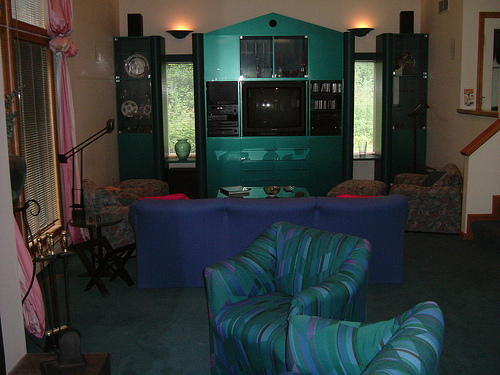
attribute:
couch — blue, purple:
[171, 212, 255, 243]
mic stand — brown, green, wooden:
[70, 137, 106, 224]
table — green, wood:
[87, 211, 115, 230]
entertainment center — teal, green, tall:
[212, 23, 330, 173]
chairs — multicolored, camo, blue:
[105, 181, 154, 202]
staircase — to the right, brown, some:
[469, 182, 490, 240]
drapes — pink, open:
[43, 68, 80, 132]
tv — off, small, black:
[254, 82, 297, 133]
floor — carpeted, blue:
[119, 316, 158, 346]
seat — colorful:
[62, 235, 123, 268]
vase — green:
[172, 136, 194, 158]